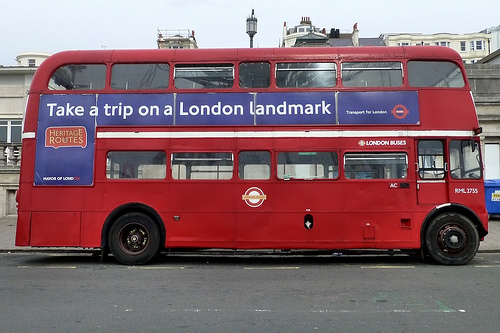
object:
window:
[339, 59, 405, 90]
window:
[405, 58, 468, 91]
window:
[104, 149, 169, 181]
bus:
[13, 45, 488, 268]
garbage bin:
[480, 178, 499, 222]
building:
[0, 6, 498, 252]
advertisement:
[30, 89, 419, 187]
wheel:
[422, 211, 480, 268]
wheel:
[106, 210, 160, 267]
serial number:
[452, 186, 478, 194]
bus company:
[356, 137, 410, 148]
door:
[413, 138, 449, 206]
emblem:
[240, 186, 266, 210]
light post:
[244, 8, 257, 49]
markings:
[113, 295, 467, 316]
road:
[0, 251, 499, 331]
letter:
[45, 101, 57, 116]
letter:
[55, 106, 64, 118]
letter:
[64, 94, 76, 121]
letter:
[86, 106, 99, 119]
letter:
[73, 106, 85, 117]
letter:
[101, 103, 112, 117]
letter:
[117, 101, 123, 117]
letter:
[121, 105, 133, 121]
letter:
[231, 105, 245, 117]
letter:
[135, 105, 150, 118]